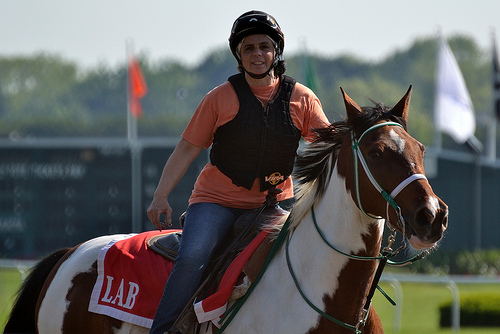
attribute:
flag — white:
[435, 43, 477, 143]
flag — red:
[127, 52, 146, 115]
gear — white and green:
[283, 120, 447, 330]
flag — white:
[437, 42, 482, 145]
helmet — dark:
[227, 11, 280, 49]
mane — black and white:
[265, 99, 400, 253]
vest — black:
[211, 73, 300, 191]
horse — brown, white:
[3, 85, 447, 331]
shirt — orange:
[180, 68, 328, 213]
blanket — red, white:
[84, 221, 277, 326]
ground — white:
[396, 71, 451, 150]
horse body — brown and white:
[20, 158, 396, 331]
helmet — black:
[229, 10, 284, 55]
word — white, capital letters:
[97, 275, 145, 308]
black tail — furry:
[6, 230, 93, 327]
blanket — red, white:
[85, 250, 132, 302]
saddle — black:
[222, 182, 382, 259]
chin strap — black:
[241, 64, 273, 83]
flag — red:
[127, 54, 147, 121]